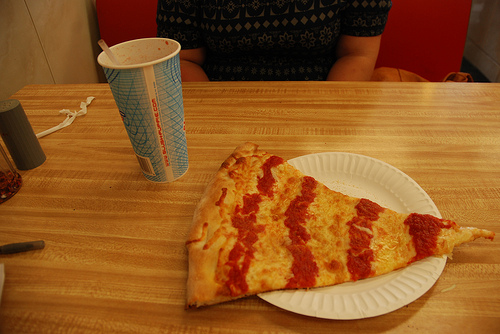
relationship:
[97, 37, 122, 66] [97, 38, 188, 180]
straw in cup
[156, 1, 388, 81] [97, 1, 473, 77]
woman on bench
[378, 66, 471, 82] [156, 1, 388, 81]
bag next to woman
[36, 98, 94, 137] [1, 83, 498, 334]
straw paper on table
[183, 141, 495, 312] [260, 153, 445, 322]
pizza on plate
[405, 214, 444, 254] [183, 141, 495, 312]
sauce on pizza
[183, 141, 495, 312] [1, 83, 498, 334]
pizza on table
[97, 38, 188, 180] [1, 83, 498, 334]
cup on table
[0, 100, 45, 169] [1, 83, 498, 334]
pepper shaker on table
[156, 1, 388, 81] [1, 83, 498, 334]
woman sitting behind table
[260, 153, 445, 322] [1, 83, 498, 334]
plate on table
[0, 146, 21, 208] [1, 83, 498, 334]
pepper on table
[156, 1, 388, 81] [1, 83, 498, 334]
woman sitting at table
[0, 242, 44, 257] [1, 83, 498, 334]
pen on table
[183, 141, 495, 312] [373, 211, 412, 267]
pizza with melted cheese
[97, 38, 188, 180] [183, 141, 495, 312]
cup and a pizza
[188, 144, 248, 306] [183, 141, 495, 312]
crust on pizza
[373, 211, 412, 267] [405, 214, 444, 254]
cheese and sauce